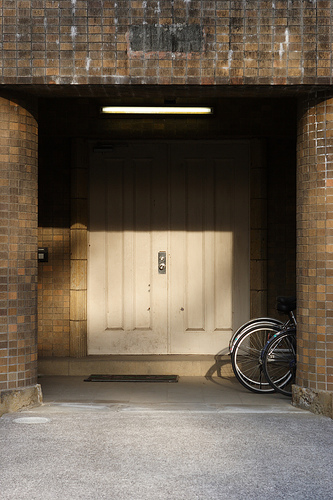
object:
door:
[87, 139, 250, 357]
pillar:
[291, 90, 333, 418]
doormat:
[90, 372, 180, 383]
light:
[101, 105, 212, 116]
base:
[0, 382, 44, 415]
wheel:
[230, 317, 294, 388]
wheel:
[263, 327, 299, 396]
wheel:
[232, 316, 297, 393]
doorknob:
[158, 251, 166, 275]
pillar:
[0, 88, 44, 414]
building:
[0, 0, 333, 421]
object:
[98, 120, 177, 131]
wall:
[33, 128, 294, 383]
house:
[0, 0, 333, 419]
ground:
[0, 370, 333, 500]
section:
[39, 157, 332, 365]